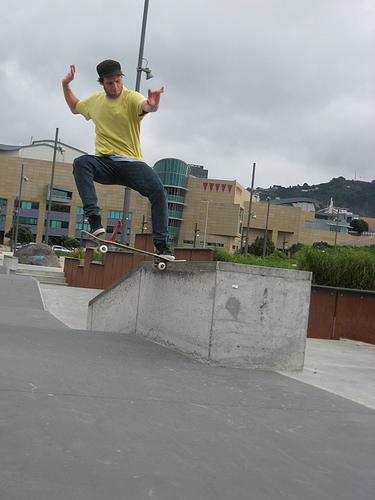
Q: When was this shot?
A: Daytime.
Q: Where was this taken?
A: Skatepark.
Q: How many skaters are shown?
A: 1.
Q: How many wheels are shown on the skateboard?
A: 4.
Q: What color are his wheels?
A: White.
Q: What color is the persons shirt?
A: Yellow.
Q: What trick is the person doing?
A: Grind.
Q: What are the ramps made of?
A: Concrete.